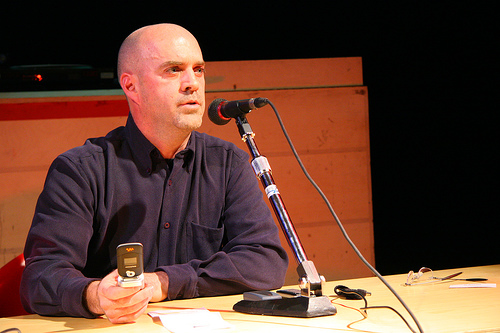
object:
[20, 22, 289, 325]
man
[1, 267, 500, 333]
table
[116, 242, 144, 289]
cell phone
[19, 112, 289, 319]
shirt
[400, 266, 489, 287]
glasses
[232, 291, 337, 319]
base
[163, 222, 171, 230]
buttons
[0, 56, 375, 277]
bench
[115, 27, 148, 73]
hair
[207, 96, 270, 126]
microphone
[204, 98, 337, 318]
stand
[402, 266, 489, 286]
pair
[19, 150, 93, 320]
long sleeves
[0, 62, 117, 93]
black box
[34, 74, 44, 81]
red light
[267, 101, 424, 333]
cord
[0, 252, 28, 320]
chair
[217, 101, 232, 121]
red band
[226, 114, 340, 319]
metal stand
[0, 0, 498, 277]
black stage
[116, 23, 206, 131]
head